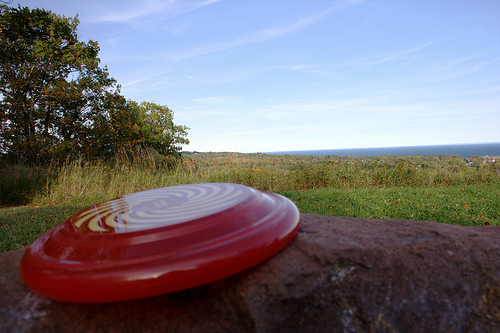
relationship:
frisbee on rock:
[108, 184, 245, 259] [343, 240, 454, 315]